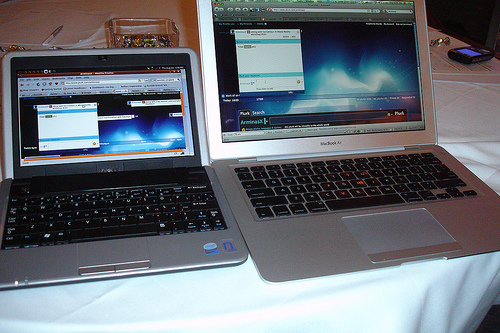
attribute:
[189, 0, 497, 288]
laptop — grey 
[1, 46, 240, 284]
laptop — grey , smaller 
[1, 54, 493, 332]
cloth — WHITE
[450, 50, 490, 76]
phone — LIT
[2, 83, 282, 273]
laptop — SMALL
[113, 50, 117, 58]
bowl — SQUARE, GLAss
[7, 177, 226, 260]
keyboard — BLACK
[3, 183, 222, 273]
keyboard — BLACK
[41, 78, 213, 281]
keyboard — BLACK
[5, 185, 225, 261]
keyboard — BLACK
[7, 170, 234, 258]
keyboard — BLACK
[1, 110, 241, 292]
keyboard — BLACK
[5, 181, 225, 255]
keyboard — BLACK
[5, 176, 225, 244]
keyboard — BLACK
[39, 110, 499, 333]
tablecloth — WHITE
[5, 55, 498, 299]
laptops — ON